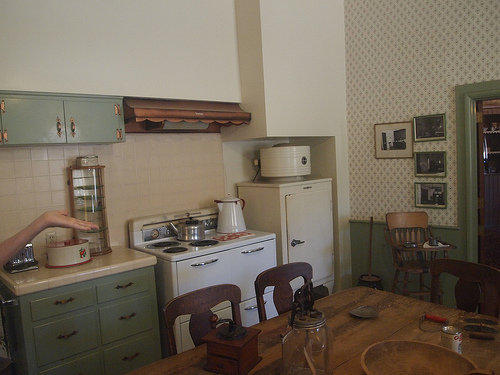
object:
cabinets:
[0, 90, 128, 146]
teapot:
[167, 214, 206, 241]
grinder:
[202, 324, 265, 375]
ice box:
[234, 180, 337, 303]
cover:
[44, 238, 89, 248]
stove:
[129, 212, 276, 355]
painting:
[372, 121, 412, 160]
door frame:
[456, 83, 476, 261]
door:
[285, 187, 334, 290]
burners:
[161, 246, 188, 253]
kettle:
[213, 192, 248, 232]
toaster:
[1, 242, 40, 275]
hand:
[41, 209, 99, 231]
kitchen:
[0, 0, 500, 375]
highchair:
[380, 210, 457, 298]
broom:
[358, 215, 382, 287]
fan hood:
[119, 98, 251, 133]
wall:
[344, 0, 499, 226]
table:
[130, 285, 499, 373]